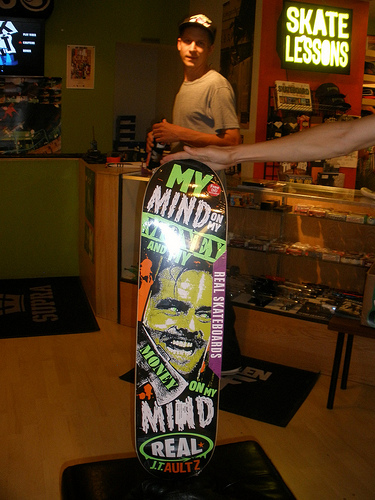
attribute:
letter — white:
[137, 398, 169, 434]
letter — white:
[176, 195, 195, 223]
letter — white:
[148, 186, 171, 215]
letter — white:
[193, 396, 214, 425]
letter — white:
[174, 400, 200, 430]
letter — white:
[173, 434, 189, 458]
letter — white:
[163, 436, 177, 459]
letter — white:
[163, 402, 175, 430]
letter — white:
[139, 400, 164, 434]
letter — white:
[198, 396, 208, 425]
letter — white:
[150, 436, 167, 457]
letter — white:
[174, 196, 191, 222]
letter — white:
[177, 438, 189, 458]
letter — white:
[189, 437, 203, 454]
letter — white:
[193, 199, 208, 228]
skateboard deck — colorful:
[131, 163, 243, 490]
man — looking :
[178, 16, 235, 388]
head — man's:
[178, 14, 215, 65]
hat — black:
[172, 16, 218, 35]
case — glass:
[237, 193, 360, 323]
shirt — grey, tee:
[179, 84, 233, 149]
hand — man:
[143, 123, 170, 160]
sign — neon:
[287, 2, 348, 74]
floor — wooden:
[14, 342, 121, 473]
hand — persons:
[164, 140, 227, 176]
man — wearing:
[172, 8, 236, 376]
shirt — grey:
[170, 84, 239, 154]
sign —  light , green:
[275, 8, 352, 76]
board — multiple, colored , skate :
[131, 162, 227, 477]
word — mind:
[139, 395, 213, 433]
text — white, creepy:
[143, 408, 209, 422]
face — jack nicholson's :
[141, 270, 213, 368]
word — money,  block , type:
[133, 341, 177, 395]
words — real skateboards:
[212, 264, 220, 368]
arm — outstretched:
[176, 124, 363, 156]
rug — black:
[225, 352, 293, 424]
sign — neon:
[279, 1, 363, 70]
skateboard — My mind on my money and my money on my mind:
[132, 155, 224, 484]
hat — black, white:
[176, 9, 223, 41]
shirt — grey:
[170, 67, 247, 181]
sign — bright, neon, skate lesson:
[272, 0, 355, 79]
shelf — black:
[114, 112, 135, 131]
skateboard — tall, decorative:
[122, 154, 240, 484]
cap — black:
[173, 10, 220, 44]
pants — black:
[221, 289, 244, 372]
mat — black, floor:
[0, 272, 103, 340]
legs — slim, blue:
[320, 330, 358, 411]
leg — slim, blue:
[335, 334, 355, 391]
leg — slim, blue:
[321, 330, 346, 410]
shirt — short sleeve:
[170, 65, 240, 197]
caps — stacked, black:
[315, 79, 350, 114]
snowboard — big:
[133, 155, 227, 474]